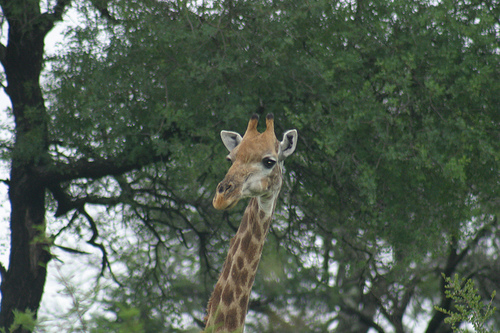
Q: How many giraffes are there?
A: One.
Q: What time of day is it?
A: Afternoon.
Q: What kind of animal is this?
A: A giraffe.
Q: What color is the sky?
A: Grey.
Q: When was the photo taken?
A: Daytime.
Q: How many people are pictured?
A: None.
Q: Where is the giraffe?
A: Among trees.